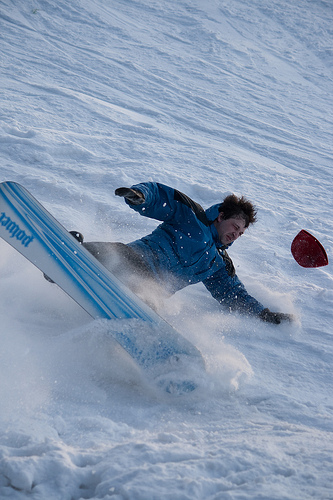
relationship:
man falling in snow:
[45, 180, 295, 359] [1, 1, 331, 496]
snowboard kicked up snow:
[3, 176, 210, 409] [1, 1, 331, 496]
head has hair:
[211, 194, 259, 250] [220, 191, 257, 226]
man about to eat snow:
[45, 180, 295, 359] [1, 1, 331, 496]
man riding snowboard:
[45, 180, 295, 359] [3, 176, 210, 409]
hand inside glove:
[110, 183, 151, 212] [112, 181, 146, 210]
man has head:
[45, 180, 295, 359] [211, 194, 259, 250]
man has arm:
[45, 180, 295, 359] [117, 180, 206, 222]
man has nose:
[45, 180, 295, 359] [229, 231, 240, 241]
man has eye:
[45, 180, 295, 359] [231, 222, 241, 234]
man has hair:
[45, 180, 295, 359] [220, 191, 257, 226]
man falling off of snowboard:
[45, 180, 295, 359] [3, 176, 210, 409]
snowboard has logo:
[3, 176, 210, 409] [2, 208, 38, 255]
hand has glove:
[110, 183, 151, 212] [112, 181, 146, 210]